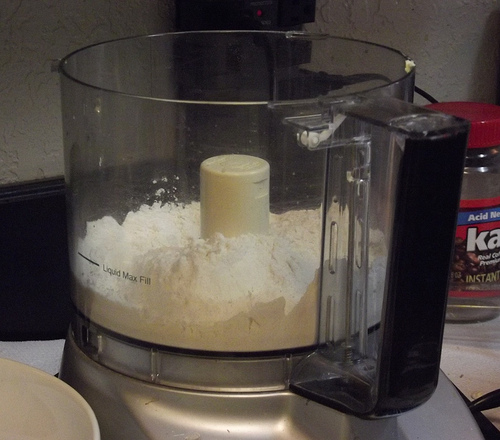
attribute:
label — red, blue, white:
[447, 118, 499, 329]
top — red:
[417, 100, 497, 152]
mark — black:
[77, 252, 99, 268]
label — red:
[449, 195, 499, 297]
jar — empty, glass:
[419, 94, 499, 320]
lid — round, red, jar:
[418, 94, 498, 164]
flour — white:
[55, 162, 390, 354]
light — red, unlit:
[254, 5, 264, 17]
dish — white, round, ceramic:
[3, 354, 104, 438]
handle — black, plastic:
[363, 103, 451, 433]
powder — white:
[58, 157, 395, 352]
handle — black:
[287, 95, 465, 419]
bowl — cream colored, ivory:
[0, 352, 102, 437]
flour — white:
[72, 174, 389, 353]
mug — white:
[8, 363, 118, 438]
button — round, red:
[255, 9, 262, 17]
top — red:
[428, 100, 484, 143]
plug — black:
[274, 62, 344, 102]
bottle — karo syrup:
[426, 98, 484, 321]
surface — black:
[191, 2, 307, 36]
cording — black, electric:
[477, 390, 484, 408]